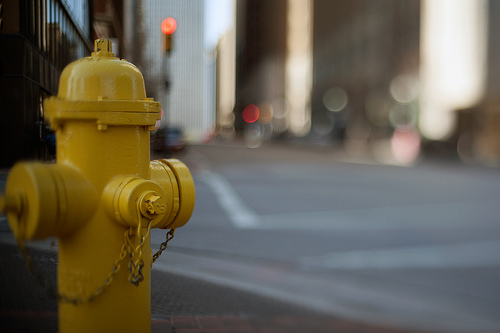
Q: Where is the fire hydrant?
A: On the street.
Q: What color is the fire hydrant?
A: Yellow.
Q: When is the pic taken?
A: Daytime.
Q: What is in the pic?
A: Fire hydrant.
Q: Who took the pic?
A: The photographer.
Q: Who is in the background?
A: No one.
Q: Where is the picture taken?
A: On the street.